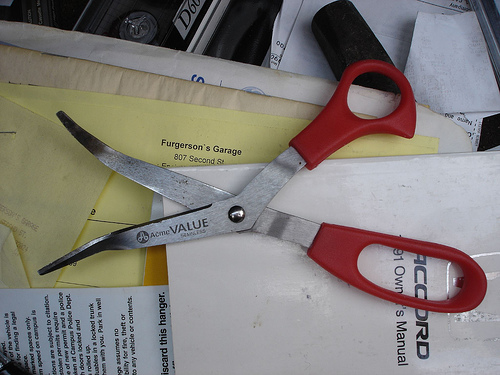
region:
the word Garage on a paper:
[211, 144, 244, 155]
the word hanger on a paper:
[151, 291, 168, 328]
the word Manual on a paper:
[395, 319, 412, 369]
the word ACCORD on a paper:
[410, 243, 437, 360]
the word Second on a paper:
[187, 153, 217, 165]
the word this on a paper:
[157, 326, 172, 348]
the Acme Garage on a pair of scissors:
[150, 228, 170, 240]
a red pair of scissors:
[33, 58, 490, 317]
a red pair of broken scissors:
[35, 57, 489, 317]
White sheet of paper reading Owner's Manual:
[145, 149, 497, 370]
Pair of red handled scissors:
[32, 59, 489, 311]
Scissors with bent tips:
[36, 58, 488, 315]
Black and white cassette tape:
[66, 2, 232, 53]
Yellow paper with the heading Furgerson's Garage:
[2, 83, 439, 293]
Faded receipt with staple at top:
[5, 89, 117, 286]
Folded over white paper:
[394, 8, 499, 120]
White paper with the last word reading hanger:
[5, 284, 176, 374]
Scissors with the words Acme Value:
[36, 59, 488, 314]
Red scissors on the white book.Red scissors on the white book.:
[199, 344, 210, 372]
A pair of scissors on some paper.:
[41, 57, 488, 320]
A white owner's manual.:
[157, 153, 498, 372]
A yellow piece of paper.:
[4, 80, 438, 287]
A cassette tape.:
[69, 3, 262, 55]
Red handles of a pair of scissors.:
[292, 60, 492, 313]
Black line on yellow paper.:
[88, 213, 137, 229]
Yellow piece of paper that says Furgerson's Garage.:
[155, 133, 246, 164]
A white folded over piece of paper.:
[400, 9, 498, 124]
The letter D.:
[173, 6, 192, 35]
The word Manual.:
[391, 318, 414, 370]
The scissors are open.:
[36, 58, 496, 309]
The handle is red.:
[311, 220, 498, 315]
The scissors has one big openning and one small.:
[305, 57, 492, 332]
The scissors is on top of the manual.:
[305, 209, 494, 371]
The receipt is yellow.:
[0, 181, 47, 266]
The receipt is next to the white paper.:
[4, 223, 51, 354]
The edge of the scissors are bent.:
[37, 237, 103, 289]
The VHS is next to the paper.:
[69, 4, 269, 116]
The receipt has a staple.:
[0, 124, 27, 146]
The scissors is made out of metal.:
[134, 162, 193, 201]